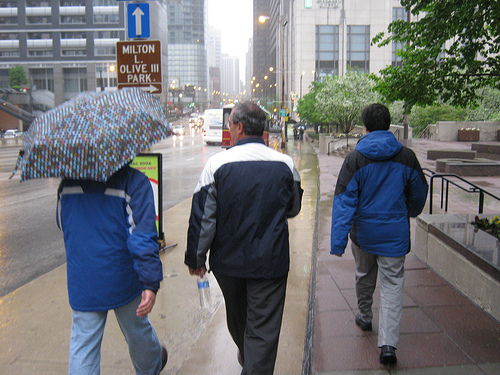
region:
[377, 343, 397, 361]
A shoe on a man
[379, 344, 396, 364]
a black shoe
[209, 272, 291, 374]
Black pants worn by a man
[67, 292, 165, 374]
Blue pants worn by a man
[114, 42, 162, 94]
A street sign outside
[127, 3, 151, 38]
a blue street sign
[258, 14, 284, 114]
A street light that is lit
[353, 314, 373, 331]
A left shoe on a foot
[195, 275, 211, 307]
A water bottle in hand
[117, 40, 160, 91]
A brown street sign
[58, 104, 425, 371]
People are walking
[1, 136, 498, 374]
The ground is wet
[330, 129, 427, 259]
Jacket is blue and black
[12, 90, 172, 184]
A multi colored umbrella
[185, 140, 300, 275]
Jacket is blue and white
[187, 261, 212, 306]
Man is holding a bottle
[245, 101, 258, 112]
Man has a bald spot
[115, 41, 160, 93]
Brown and white sign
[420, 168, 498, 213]
Dark metal railing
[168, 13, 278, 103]
Street lights are on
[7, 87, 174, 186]
a mn walking under an umbrella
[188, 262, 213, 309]
man holding a bottle of water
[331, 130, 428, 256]
man wearing a blue and black winter coat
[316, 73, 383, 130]
a tree with white flowers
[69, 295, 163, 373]
a man with blue jeans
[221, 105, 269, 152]
a red bus on the street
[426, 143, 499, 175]
stone benches in a park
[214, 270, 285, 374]
a man wearing black pants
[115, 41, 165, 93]
a brown sign on a pole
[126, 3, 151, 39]
a blue and white sign on a pole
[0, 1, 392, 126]
buildings on city street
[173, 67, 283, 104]
glowing lights on sides of street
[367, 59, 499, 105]
green leaves on branch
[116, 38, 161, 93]
brown sign with white letters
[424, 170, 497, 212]
black metal stair rails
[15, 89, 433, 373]
backs of three walking people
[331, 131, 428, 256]
black and blue coat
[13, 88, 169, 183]
top of open umbrella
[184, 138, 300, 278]
jacket with white shoulders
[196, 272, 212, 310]
blue label on water bottle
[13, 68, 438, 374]
three men walking on a sidewalk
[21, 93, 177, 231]
a man holding a umbrella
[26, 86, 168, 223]
a man under a umbrella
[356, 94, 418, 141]
a man with dark hair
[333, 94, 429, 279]
a man wearing a blue and black jacket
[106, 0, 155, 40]
a blue and white street sign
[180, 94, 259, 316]
a man carrying a water bottle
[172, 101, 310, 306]
a man wearing a blue and white jacket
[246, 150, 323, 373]
a concrete side walk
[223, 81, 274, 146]
a man with grey hair